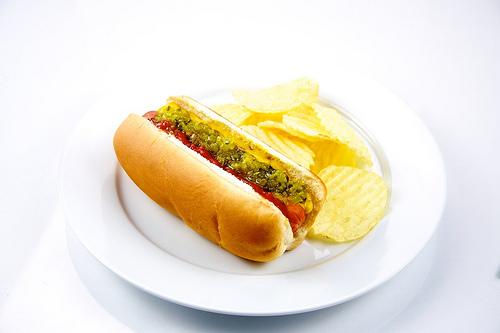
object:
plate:
[64, 81, 448, 319]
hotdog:
[112, 95, 327, 264]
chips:
[209, 78, 389, 244]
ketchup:
[147, 118, 290, 218]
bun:
[113, 94, 329, 263]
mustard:
[153, 102, 316, 213]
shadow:
[67, 223, 467, 333]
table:
[0, 0, 500, 333]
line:
[212, 213, 222, 243]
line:
[294, 213, 302, 222]